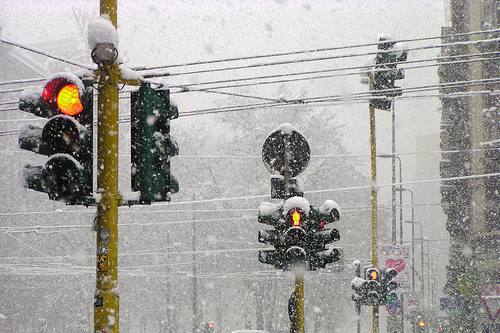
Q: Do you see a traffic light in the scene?
A: Yes, there is a traffic light.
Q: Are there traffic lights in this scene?
A: Yes, there is a traffic light.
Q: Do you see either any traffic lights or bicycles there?
A: Yes, there is a traffic light.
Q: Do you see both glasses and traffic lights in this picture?
A: No, there is a traffic light but no glasses.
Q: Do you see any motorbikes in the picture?
A: No, there are no motorbikes.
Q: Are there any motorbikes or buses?
A: No, there are no motorbikes or buses.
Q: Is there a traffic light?
A: Yes, there is a traffic light.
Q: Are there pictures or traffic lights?
A: Yes, there is a traffic light.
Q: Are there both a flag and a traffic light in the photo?
A: No, there is a traffic light but no flags.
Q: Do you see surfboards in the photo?
A: No, there are no surfboards.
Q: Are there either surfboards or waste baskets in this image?
A: No, there are no surfboards or waste baskets.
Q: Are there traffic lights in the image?
A: Yes, there is a traffic light.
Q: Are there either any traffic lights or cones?
A: Yes, there is a traffic light.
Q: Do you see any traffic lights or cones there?
A: Yes, there is a traffic light.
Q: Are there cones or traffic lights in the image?
A: Yes, there is a traffic light.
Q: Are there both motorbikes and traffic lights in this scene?
A: No, there is a traffic light but no motorcycles.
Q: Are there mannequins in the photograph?
A: No, there are no mannequins.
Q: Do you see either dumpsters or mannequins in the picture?
A: No, there are no mannequins or dumpsters.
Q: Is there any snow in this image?
A: Yes, there is snow.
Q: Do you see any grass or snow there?
A: Yes, there is snow.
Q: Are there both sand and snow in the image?
A: No, there is snow but no sand.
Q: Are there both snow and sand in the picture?
A: No, there is snow but no sand.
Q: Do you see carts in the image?
A: No, there are no carts.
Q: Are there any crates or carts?
A: No, there are no carts or crates.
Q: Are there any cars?
A: No, there are no cars.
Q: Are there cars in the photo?
A: No, there are no cars.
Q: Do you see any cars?
A: No, there are no cars.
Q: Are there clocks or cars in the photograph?
A: No, there are no cars or clocks.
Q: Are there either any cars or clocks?
A: No, there are no cars or clocks.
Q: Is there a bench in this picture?
A: No, there are no benches.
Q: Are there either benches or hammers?
A: No, there are no benches or hammers.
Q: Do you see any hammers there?
A: No, there are no hammers.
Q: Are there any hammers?
A: No, there are no hammers.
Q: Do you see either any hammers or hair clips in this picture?
A: No, there are no hammers or hair clips.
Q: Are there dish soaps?
A: No, there are no dish soaps.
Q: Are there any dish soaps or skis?
A: No, there are no dish soaps or skis.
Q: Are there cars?
A: No, there are no cars.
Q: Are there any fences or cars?
A: No, there are no cars or fences.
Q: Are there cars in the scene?
A: No, there are no cars.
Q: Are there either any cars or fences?
A: No, there are no cars or fences.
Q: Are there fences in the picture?
A: No, there are no fences.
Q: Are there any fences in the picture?
A: No, there are no fences.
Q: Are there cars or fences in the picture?
A: No, there are no fences or cars.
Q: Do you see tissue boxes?
A: No, there are no tissue boxes.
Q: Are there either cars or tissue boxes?
A: No, there are no tissue boxes or cars.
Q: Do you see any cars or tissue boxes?
A: No, there are no tissue boxes or cars.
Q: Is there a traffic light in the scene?
A: Yes, there is a traffic light.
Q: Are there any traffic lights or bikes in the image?
A: Yes, there is a traffic light.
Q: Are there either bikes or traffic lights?
A: Yes, there is a traffic light.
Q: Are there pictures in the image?
A: No, there are no pictures.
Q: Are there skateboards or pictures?
A: No, there are no pictures or skateboards.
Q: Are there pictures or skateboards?
A: No, there are no pictures or skateboards.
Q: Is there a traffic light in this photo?
A: Yes, there is a traffic light.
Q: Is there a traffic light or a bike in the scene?
A: Yes, there is a traffic light.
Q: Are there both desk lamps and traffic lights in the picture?
A: No, there is a traffic light but no desk lamps.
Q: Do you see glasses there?
A: No, there are no glasses.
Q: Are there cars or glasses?
A: No, there are no glasses or cars.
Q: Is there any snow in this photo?
A: Yes, there is snow.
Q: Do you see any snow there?
A: Yes, there is snow.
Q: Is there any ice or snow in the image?
A: Yes, there is snow.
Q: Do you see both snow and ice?
A: No, there is snow but no ice.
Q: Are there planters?
A: No, there are no planters.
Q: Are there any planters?
A: No, there are no planters.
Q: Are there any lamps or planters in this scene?
A: No, there are no planters or lamps.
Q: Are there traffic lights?
A: Yes, there is a traffic light.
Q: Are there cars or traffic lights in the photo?
A: Yes, there is a traffic light.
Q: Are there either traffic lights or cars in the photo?
A: Yes, there is a traffic light.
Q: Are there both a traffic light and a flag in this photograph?
A: No, there is a traffic light but no flags.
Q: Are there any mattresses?
A: No, there are no mattresses.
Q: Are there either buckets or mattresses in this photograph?
A: No, there are no mattresses or buckets.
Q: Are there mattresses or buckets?
A: No, there are no mattresses or buckets.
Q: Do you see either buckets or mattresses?
A: No, there are no mattresses or buckets.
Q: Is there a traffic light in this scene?
A: Yes, there is a traffic light.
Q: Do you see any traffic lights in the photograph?
A: Yes, there is a traffic light.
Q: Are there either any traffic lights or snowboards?
A: Yes, there is a traffic light.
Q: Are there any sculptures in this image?
A: No, there are no sculptures.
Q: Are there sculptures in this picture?
A: No, there are no sculptures.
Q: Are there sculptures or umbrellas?
A: No, there are no sculptures or umbrellas.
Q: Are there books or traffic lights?
A: Yes, there is a traffic light.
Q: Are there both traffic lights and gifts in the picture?
A: No, there is a traffic light but no gifts.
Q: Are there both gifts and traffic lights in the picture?
A: No, there is a traffic light but no gifts.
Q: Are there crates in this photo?
A: No, there are no crates.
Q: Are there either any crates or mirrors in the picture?
A: No, there are no crates or mirrors.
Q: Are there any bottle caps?
A: No, there are no bottle caps.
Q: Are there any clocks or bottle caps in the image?
A: No, there are no bottle caps or clocks.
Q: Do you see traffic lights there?
A: Yes, there is a traffic light.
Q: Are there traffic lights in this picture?
A: Yes, there is a traffic light.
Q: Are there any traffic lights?
A: Yes, there is a traffic light.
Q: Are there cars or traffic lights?
A: Yes, there is a traffic light.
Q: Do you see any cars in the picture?
A: No, there are no cars.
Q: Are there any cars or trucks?
A: No, there are no cars or trucks.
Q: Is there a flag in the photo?
A: No, there are no flags.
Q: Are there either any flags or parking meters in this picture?
A: No, there are no flags or parking meters.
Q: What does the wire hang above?
A: The wire hangs above the road.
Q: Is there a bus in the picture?
A: No, there are no buses.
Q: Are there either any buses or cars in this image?
A: No, there are no buses or cars.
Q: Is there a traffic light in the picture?
A: Yes, there is a traffic light.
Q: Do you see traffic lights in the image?
A: Yes, there is a traffic light.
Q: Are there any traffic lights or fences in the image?
A: Yes, there is a traffic light.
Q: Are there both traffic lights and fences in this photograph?
A: No, there is a traffic light but no fences.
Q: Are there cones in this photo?
A: No, there are no cones.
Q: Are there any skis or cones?
A: No, there are no cones or skis.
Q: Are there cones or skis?
A: No, there are no cones or skis.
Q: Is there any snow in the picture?
A: Yes, there is snow.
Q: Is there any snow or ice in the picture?
A: Yes, there is snow.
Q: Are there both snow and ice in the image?
A: No, there is snow but no ice.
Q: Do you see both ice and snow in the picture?
A: No, there is snow but no ice.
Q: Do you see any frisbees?
A: No, there are no frisbees.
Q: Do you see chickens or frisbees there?
A: No, there are no frisbees or chickens.